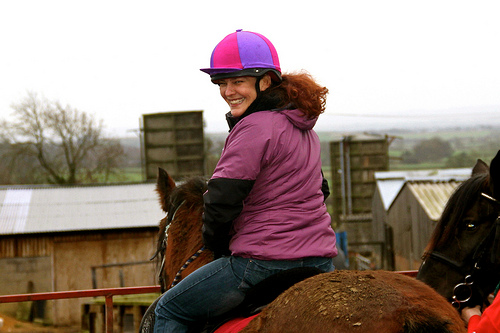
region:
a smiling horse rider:
[132, 23, 477, 327]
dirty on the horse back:
[310, 275, 364, 327]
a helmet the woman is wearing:
[198, 25, 285, 81]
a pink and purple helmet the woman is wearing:
[197, 26, 286, 83]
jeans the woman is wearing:
[150, 251, 347, 330]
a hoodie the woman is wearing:
[200, 100, 340, 263]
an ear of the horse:
[152, 163, 177, 213]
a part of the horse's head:
[416, 146, 499, 313]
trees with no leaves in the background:
[3, 95, 117, 183]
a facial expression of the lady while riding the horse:
[212, 75, 264, 120]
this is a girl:
[201, 29, 336, 275]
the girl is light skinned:
[233, 88, 257, 105]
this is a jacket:
[269, 132, 317, 217]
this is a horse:
[312, 286, 392, 327]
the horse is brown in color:
[299, 283, 404, 329]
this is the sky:
[337, 17, 419, 89]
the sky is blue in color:
[118, 79, 158, 103]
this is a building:
[26, 178, 121, 258]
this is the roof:
[46, 200, 93, 220]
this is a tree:
[48, 105, 113, 170]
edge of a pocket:
[233, 265, 245, 288]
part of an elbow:
[206, 175, 242, 225]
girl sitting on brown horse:
[115, 0, 330, 315]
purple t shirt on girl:
[187, 104, 399, 271]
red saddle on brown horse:
[190, 279, 250, 331]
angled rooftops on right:
[391, 163, 474, 251]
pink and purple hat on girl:
[181, 30, 313, 82]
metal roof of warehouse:
[395, 173, 491, 230]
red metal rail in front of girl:
[18, 280, 180, 325]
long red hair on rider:
[260, 76, 327, 127]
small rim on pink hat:
[189, 58, 221, 93]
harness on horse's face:
[154, 214, 217, 287]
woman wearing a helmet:
[180, 20, 348, 291]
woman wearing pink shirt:
[212, 20, 327, 280]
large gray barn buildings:
[370, 168, 376, 252]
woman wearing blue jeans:
[135, 15, 320, 310]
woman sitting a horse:
[182, 20, 322, 295]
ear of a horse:
[145, 160, 176, 211]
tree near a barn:
[27, 96, 107, 173]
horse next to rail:
[445, 155, 485, 300]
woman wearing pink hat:
[165, 20, 340, 275]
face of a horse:
[431, 145, 483, 285]